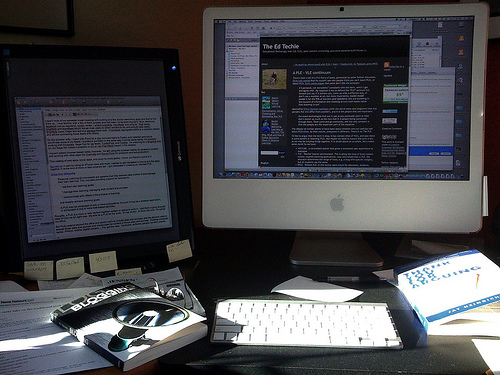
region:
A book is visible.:
[90, 278, 181, 369]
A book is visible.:
[55, 267, 149, 355]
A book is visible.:
[81, 335, 112, 365]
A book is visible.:
[47, 268, 214, 373]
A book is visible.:
[72, 310, 144, 361]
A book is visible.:
[62, 241, 182, 342]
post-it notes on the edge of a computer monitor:
[25, 242, 202, 277]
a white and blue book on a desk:
[393, 250, 498, 373]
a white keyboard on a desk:
[215, 295, 410, 359]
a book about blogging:
[53, 275, 204, 371]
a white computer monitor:
[199, 0, 493, 233]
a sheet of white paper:
[264, 280, 364, 302]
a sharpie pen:
[311, 267, 381, 287]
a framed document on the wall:
[3, 0, 83, 38]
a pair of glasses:
[138, 272, 194, 304]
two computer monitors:
[11, 11, 467, 281]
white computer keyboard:
[213, 294, 411, 374]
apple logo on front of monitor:
[323, 189, 357, 216]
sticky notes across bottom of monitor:
[24, 249, 192, 279]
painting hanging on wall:
[0, 0, 82, 40]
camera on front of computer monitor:
[330, 0, 352, 21]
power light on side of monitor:
[166, 54, 186, 77]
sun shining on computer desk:
[201, 240, 465, 371]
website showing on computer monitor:
[209, 16, 471, 179]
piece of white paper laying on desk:
[269, 264, 366, 301]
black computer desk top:
[212, 346, 460, 373]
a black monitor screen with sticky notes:
[1, 41, 196, 282]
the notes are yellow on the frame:
[10, 231, 195, 272]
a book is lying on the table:
[46, 281, 207, 369]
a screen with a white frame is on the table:
[196, 2, 488, 232]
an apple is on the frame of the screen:
[327, 187, 352, 215]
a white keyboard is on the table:
[207, 290, 402, 352]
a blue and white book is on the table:
[387, 241, 497, 341]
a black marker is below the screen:
[307, 270, 379, 285]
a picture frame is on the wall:
[0, 1, 76, 37]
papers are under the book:
[1, 280, 206, 364]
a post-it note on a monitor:
[164, 236, 196, 263]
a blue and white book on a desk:
[390, 248, 498, 345]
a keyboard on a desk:
[205, 294, 403, 355]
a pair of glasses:
[132, 265, 211, 318]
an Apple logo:
[326, 190, 347, 213]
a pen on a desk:
[302, 270, 396, 288]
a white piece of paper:
[265, 266, 367, 309]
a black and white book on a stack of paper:
[50, 278, 213, 364]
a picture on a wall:
[0, 0, 86, 39]